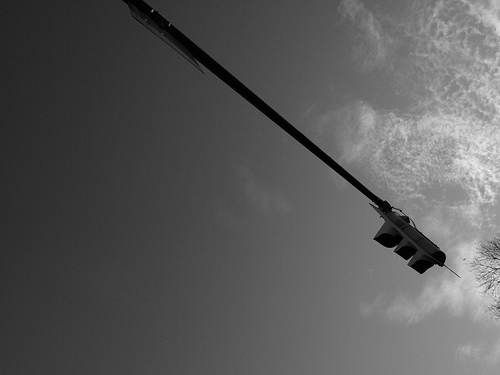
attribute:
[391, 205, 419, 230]
wire — sticking out, electrical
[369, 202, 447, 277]
traffic signal — solo, angled, metal, mounted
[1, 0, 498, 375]
sky — cloudy, clear, grey, lacy, lightening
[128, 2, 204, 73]
street sign — solo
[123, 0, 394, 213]
pole — black, metal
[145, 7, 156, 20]
bracket — mounting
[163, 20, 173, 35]
bracket — mounting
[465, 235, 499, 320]
tree — bare, leafless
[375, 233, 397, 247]
light — protruding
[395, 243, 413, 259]
light — protruding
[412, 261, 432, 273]
light — protruding